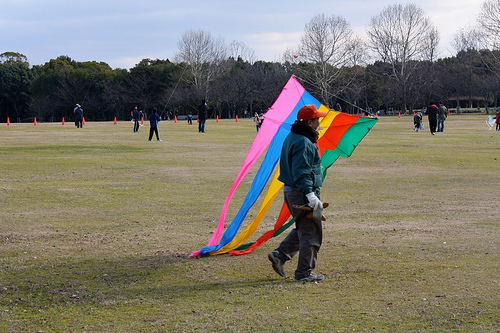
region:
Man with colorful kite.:
[190, 64, 373, 261]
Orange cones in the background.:
[9, 106, 464, 131]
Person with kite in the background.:
[485, 110, 497, 132]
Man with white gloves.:
[304, 183, 327, 217]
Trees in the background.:
[0, 0, 499, 127]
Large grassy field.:
[5, 116, 497, 329]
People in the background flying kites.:
[70, 98, 456, 138]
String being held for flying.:
[165, 33, 195, 114]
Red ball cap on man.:
[295, 105, 329, 125]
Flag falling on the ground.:
[186, 67, 387, 262]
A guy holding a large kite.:
[266, 107, 326, 279]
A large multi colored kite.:
[190, 73, 378, 256]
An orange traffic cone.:
[5, 118, 10, 125]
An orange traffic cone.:
[32, 116, 39, 125]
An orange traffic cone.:
[60, 118, 65, 124]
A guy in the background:
[75, 105, 83, 129]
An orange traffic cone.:
[80, 117, 87, 126]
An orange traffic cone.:
[112, 118, 117, 124]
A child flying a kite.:
[147, 106, 161, 141]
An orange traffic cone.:
[398, 112, 401, 117]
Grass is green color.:
[36, 154, 148, 316]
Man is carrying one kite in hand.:
[191, 68, 359, 253]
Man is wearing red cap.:
[281, 95, 341, 147]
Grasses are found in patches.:
[25, 125, 480, 320]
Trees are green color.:
[8, 56, 499, 133]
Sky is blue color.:
[26, 4, 239, 43]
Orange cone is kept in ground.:
[1, 107, 473, 144]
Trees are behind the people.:
[6, 43, 468, 125]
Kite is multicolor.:
[268, 78, 360, 236]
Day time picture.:
[32, 26, 484, 311]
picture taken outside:
[43, 45, 435, 297]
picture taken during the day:
[29, 15, 489, 164]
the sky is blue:
[54, 19, 187, 75]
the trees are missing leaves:
[283, 14, 442, 58]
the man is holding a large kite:
[219, 125, 401, 323]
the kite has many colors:
[224, 93, 397, 295]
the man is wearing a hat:
[286, 90, 326, 133]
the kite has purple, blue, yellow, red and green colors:
[210, 57, 367, 268]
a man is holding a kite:
[139, 69, 193, 181]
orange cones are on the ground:
[23, 107, 205, 182]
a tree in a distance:
[5, 52, 28, 67]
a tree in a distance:
[1, 60, 32, 115]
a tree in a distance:
[33, 62, 64, 109]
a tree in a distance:
[58, 56, 93, 103]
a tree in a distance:
[101, 69, 134, 114]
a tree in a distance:
[131, 51, 159, 93]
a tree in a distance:
[176, 30, 223, 130]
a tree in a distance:
[229, 40, 263, 119]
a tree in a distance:
[292, 6, 370, 130]